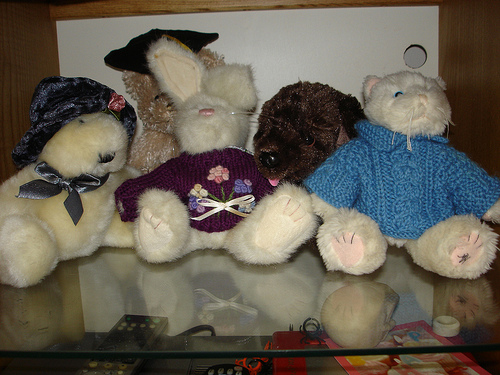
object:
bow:
[14, 159, 104, 227]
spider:
[299, 316, 328, 345]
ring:
[302, 317, 322, 337]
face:
[363, 68, 453, 137]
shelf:
[0, 244, 500, 358]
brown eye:
[299, 130, 316, 147]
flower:
[233, 177, 253, 194]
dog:
[252, 80, 369, 187]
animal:
[298, 69, 500, 283]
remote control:
[72, 313, 167, 375]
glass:
[0, 235, 500, 360]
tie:
[14, 160, 110, 225]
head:
[359, 67, 453, 137]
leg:
[0, 209, 56, 292]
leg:
[406, 213, 500, 281]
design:
[206, 164, 230, 202]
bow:
[186, 194, 258, 222]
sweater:
[303, 120, 500, 239]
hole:
[403, 43, 428, 70]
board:
[55, 4, 439, 333]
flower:
[188, 182, 209, 200]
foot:
[314, 205, 390, 276]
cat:
[0, 74, 143, 291]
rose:
[105, 90, 126, 114]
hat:
[10, 74, 136, 170]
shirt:
[111, 147, 276, 236]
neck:
[33, 158, 111, 195]